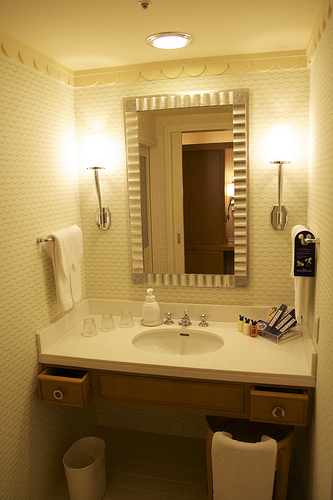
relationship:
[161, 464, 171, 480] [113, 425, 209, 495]
tile in floor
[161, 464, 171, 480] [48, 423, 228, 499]
tile part of floor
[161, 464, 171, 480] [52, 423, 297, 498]
tile part of floor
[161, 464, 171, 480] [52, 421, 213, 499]
tile part of floor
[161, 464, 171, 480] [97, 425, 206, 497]
tile part of floor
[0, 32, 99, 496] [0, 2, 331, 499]
wall part of building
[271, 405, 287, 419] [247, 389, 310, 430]
handle on drawer